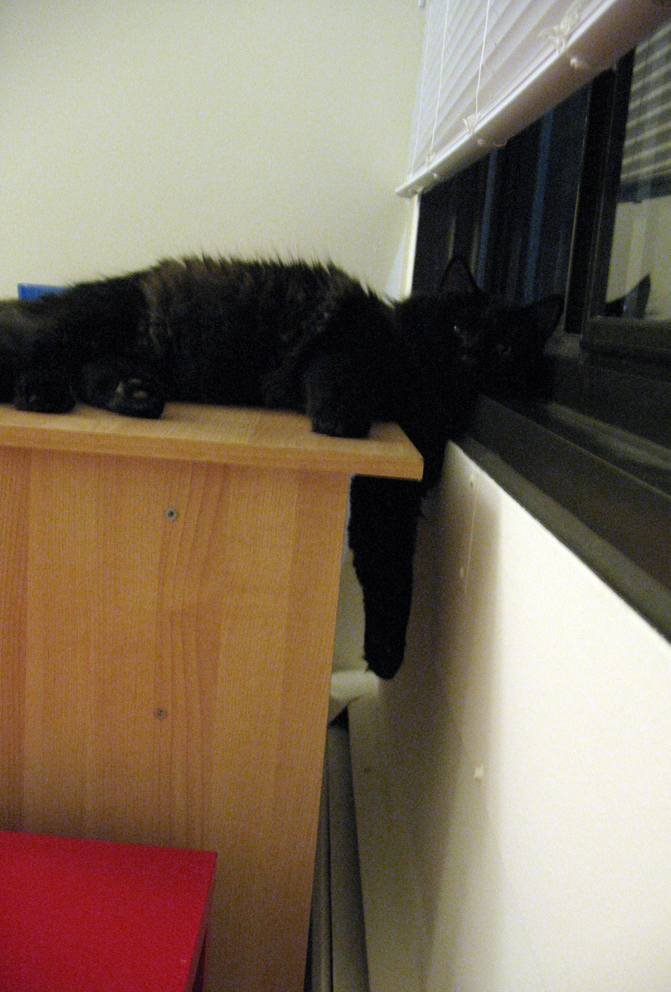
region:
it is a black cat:
[16, 248, 561, 470]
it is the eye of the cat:
[448, 315, 468, 336]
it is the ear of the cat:
[441, 257, 477, 300]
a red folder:
[1, 828, 216, 989]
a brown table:
[5, 391, 396, 807]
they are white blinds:
[386, 15, 657, 205]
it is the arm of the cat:
[352, 483, 417, 672]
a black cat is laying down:
[5, 243, 536, 440]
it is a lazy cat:
[8, 251, 524, 448]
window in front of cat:
[407, 2, 669, 591]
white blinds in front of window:
[389, 1, 668, 214]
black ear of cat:
[430, 246, 483, 295]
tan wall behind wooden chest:
[2, 0, 428, 299]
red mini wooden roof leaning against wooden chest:
[1, 822, 223, 988]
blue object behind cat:
[9, 273, 78, 306]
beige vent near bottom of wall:
[307, 663, 422, 989]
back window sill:
[474, 388, 668, 588]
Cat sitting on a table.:
[163, 227, 649, 505]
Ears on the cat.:
[392, 239, 657, 423]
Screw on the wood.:
[125, 475, 234, 548]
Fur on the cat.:
[73, 250, 370, 388]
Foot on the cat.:
[67, 341, 212, 478]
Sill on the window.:
[445, 288, 638, 578]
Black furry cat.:
[120, 214, 629, 503]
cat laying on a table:
[1, 234, 574, 715]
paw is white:
[325, 646, 387, 709]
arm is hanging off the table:
[331, 426, 447, 713]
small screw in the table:
[157, 499, 194, 536]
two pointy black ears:
[441, 246, 566, 337]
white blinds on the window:
[397, 1, 670, 207]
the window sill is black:
[437, 369, 670, 638]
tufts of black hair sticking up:
[169, 239, 327, 280]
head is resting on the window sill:
[421, 257, 575, 402]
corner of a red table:
[186, 844, 230, 861]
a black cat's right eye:
[449, 321, 469, 341]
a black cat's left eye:
[493, 338, 512, 359]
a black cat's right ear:
[434, 255, 479, 296]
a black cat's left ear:
[526, 292, 566, 340]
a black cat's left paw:
[364, 620, 407, 676]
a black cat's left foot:
[81, 356, 164, 416]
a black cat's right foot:
[11, 366, 71, 412]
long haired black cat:
[2, 245, 563, 679]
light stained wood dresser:
[0, 400, 421, 989]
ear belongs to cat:
[434, 254, 476, 298]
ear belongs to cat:
[528, 291, 565, 343]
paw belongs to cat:
[364, 622, 408, 681]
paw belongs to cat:
[311, 392, 373, 444]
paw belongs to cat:
[102, 368, 164, 421]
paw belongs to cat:
[12, 369, 81, 421]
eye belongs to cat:
[448, 323, 462, 337]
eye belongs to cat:
[495, 340, 509, 356]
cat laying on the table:
[14, 221, 547, 707]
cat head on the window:
[409, 253, 577, 390]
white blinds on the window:
[402, 4, 657, 207]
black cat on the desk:
[1, 232, 556, 685]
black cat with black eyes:
[442, 309, 534, 366]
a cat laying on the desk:
[99, 163, 641, 630]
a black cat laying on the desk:
[143, 236, 302, 414]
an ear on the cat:
[412, 253, 465, 300]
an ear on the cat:
[502, 278, 571, 352]